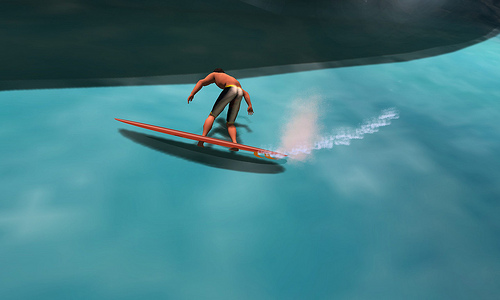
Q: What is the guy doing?
A: Surfing.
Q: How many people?
A: 1.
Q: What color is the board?
A: Red.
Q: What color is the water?
A: Blue.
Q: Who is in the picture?
A: Surfer.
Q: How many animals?
A: None.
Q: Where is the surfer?
A: On surfboard.